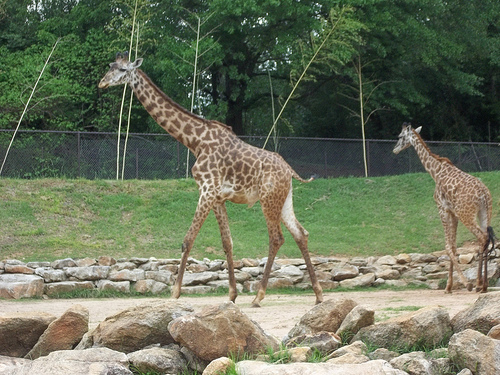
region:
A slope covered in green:
[332, 199, 364, 219]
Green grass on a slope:
[336, 196, 358, 223]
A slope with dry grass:
[59, 212, 77, 223]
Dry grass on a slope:
[70, 212, 87, 222]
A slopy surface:
[37, 200, 120, 239]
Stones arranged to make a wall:
[88, 265, 165, 282]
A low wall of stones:
[335, 262, 404, 279]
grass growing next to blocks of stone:
[75, 290, 117, 297]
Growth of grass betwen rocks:
[403, 346, 418, 349]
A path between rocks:
[19, 301, 61, 307]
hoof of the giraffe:
[316, 296, 329, 301]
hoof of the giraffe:
[254, 299, 266, 314]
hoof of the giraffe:
[445, 280, 460, 294]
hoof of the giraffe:
[473, 282, 493, 289]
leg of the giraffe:
[259, 207, 274, 293]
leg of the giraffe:
[286, 224, 327, 290]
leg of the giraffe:
[207, 207, 250, 294]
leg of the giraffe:
[170, 200, 208, 287]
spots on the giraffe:
[179, 136, 249, 187]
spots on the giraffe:
[434, 180, 479, 197]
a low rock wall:
[73, 256, 459, 296]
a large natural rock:
[173, 297, 289, 355]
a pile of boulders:
[91, 293, 276, 370]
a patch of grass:
[381, 300, 428, 312]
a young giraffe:
[391, 122, 497, 291]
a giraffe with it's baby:
[95, 45, 497, 304]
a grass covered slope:
[150, 166, 495, 264]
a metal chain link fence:
[267, 128, 498, 183]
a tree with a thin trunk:
[332, 39, 380, 179]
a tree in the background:
[185, 2, 342, 194]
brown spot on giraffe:
[131, 78, 139, 89]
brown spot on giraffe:
[141, 98, 158, 115]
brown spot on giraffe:
[158, 117, 168, 129]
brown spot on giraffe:
[166, 123, 174, 134]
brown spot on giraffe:
[175, 130, 186, 145]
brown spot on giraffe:
[184, 134, 198, 149]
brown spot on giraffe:
[183, 122, 194, 137]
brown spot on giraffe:
[192, 123, 208, 139]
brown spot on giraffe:
[229, 147, 241, 163]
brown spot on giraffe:
[198, 158, 208, 174]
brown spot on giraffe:
[135, 88, 142, 95]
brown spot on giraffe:
[138, 90, 147, 104]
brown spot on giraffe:
[155, 96, 167, 106]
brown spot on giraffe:
[163, 110, 178, 119]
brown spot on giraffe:
[169, 115, 184, 129]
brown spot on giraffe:
[199, 140, 211, 155]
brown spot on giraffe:
[227, 164, 235, 185]